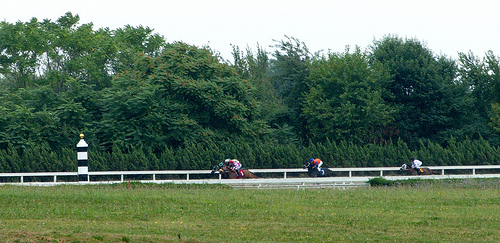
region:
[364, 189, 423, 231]
part of a ground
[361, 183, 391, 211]
part of a ground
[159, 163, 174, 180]
part of a metal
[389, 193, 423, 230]
part of a ground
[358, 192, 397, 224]
part of a ground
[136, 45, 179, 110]
part of a tree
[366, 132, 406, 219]
part of a ground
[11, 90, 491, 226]
The people are on race horses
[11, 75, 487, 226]
The people are on a horse racing track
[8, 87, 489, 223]
The riders are in a horse race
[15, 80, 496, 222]
The riders are competing very hard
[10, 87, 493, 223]
The jockeys are trying hard to win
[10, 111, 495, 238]
The horses are running very fast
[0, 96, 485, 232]
The horses are running close to trees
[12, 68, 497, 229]
The horses are running on a nice day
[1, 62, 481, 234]
The horses are enjoying the run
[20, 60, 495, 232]
The jockeys are enjoying the day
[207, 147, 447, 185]
people riding on horses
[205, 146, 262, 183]
horse rider in front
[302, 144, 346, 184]
horse rider in middle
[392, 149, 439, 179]
horse rider in back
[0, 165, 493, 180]
fence next to riders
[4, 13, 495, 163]
trees next to riders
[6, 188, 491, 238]
field next to riders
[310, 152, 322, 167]
person on horse in middle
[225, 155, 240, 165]
person on horse in front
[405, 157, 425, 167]
person on horse at end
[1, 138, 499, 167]
Green hedgerow next to a race track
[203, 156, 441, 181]
Horse riders racing on the race track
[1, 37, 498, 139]
Green trees at the side of the race track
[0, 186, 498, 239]
Grass field near the race track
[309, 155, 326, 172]
Horse rider wearing red clothing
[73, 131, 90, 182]
black and white post on the railings on the race track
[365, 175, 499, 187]
Green shrub near the race track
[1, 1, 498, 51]
Cloudy weather at the sky in the background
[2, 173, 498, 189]
White railings on the race track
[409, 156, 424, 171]
Horse rider wearing white clothing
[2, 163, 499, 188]
The white fence in the area.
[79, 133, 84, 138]
The gold ball on top of the stripe structure.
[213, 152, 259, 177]
The horse on the left.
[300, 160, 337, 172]
The horse in the middle.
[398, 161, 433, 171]
The horse on the right.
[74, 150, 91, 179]
The black and white structure.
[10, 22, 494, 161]
The trees in the background.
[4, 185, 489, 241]
The grass area where the race is taking place.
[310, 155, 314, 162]
The blue helmet the rider in the middle is wearing.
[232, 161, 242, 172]
The red and white outfit the rider in front is wearing.